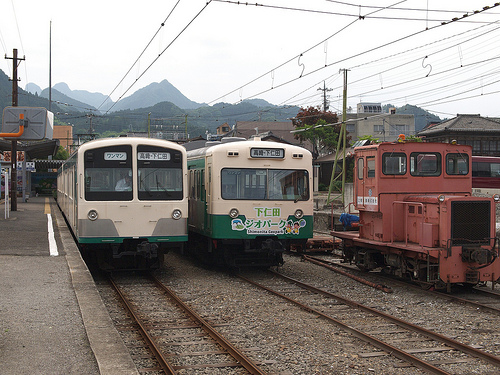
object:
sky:
[73, 12, 120, 76]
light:
[171, 209, 181, 221]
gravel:
[182, 274, 350, 374]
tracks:
[321, 267, 498, 372]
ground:
[0, 262, 76, 343]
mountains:
[0, 74, 473, 126]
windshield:
[87, 165, 182, 192]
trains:
[52, 127, 323, 271]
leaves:
[326, 132, 331, 137]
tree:
[289, 103, 351, 164]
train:
[328, 145, 499, 296]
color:
[380, 176, 466, 239]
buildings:
[214, 100, 500, 184]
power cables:
[112, 2, 484, 87]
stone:
[241, 292, 278, 342]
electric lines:
[0, 0, 497, 112]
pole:
[322, 67, 351, 209]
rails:
[131, 296, 251, 372]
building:
[340, 98, 417, 146]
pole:
[7, 41, 29, 211]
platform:
[2, 187, 144, 374]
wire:
[104, 0, 209, 116]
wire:
[213, 1, 498, 23]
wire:
[207, 0, 405, 105]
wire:
[321, 52, 498, 104]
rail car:
[51, 132, 192, 272]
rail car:
[186, 137, 320, 267]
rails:
[269, 288, 481, 368]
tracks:
[101, 274, 218, 364]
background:
[0, 15, 481, 135]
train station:
[1, 99, 481, 360]